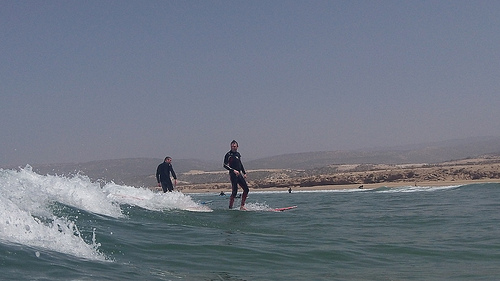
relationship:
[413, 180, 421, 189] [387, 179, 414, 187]
person on beach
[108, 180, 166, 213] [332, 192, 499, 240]
wave in sea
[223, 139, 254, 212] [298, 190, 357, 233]
man in water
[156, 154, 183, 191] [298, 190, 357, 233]
man in water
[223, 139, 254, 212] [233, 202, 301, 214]
man on surfboard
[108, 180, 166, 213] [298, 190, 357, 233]
wave in water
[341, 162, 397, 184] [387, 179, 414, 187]
hill on beach